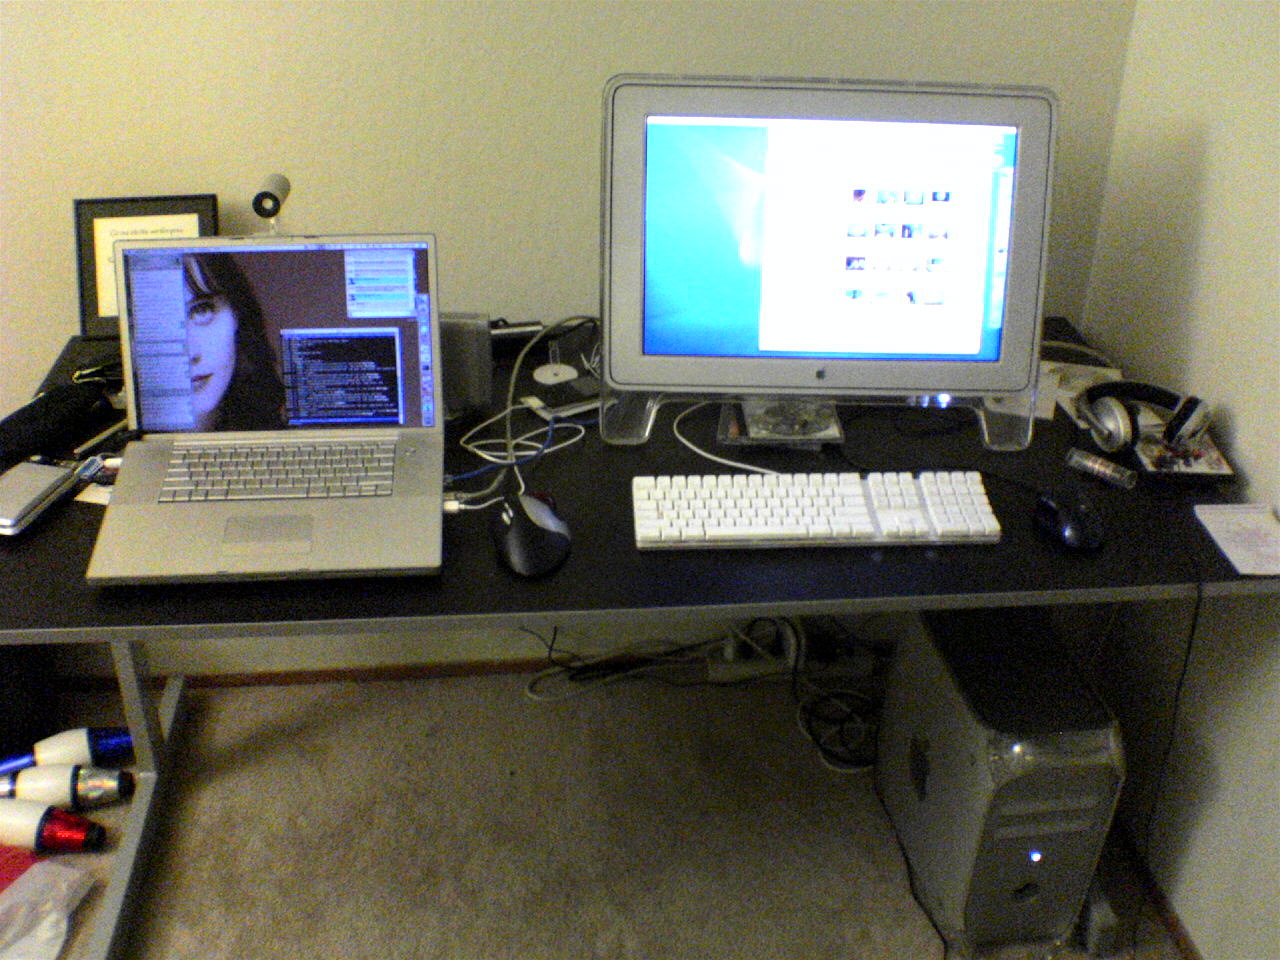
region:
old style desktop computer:
[575, 51, 1205, 937]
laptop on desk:
[53, 181, 480, 654]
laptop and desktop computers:
[57, 77, 1177, 923]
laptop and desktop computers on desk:
[55, 84, 1091, 950]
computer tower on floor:
[854, 604, 1144, 955]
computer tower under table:
[854, 567, 1135, 949]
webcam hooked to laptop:
[238, 117, 323, 288]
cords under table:
[591, 620, 914, 850]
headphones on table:
[1061, 351, 1232, 528]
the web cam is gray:
[248, 172, 291, 243]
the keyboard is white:
[630, 467, 1001, 552]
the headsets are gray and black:
[1075, 379, 1212, 450]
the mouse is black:
[1036, 477, 1107, 551]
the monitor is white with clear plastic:
[594, 75, 1060, 451]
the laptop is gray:
[84, 232, 446, 584]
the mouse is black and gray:
[491, 488, 571, 584]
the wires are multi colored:
[442, 311, 1211, 958]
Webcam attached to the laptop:
[246, 174, 293, 239]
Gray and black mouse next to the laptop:
[490, 490, 579, 585]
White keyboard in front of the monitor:
[630, 467, 999, 543]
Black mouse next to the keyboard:
[1033, 470, 1111, 557]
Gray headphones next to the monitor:
[1069, 373, 1213, 458]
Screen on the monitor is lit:
[643, 114, 1008, 368]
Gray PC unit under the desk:
[870, 620, 1120, 952]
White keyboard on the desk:
[619, 461, 1003, 548]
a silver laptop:
[87, 235, 434, 569]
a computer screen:
[605, 74, 1027, 383]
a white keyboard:
[629, 471, 987, 536]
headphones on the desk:
[1073, 376, 1201, 430]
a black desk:
[24, 331, 1272, 685]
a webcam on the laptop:
[244, 174, 297, 227]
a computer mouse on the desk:
[1020, 471, 1109, 553]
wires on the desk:
[475, 305, 612, 464]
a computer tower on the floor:
[872, 654, 1100, 931]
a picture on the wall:
[66, 201, 226, 325]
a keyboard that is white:
[627, 458, 1023, 551]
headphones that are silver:
[1058, 361, 1211, 463]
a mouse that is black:
[1034, 482, 1116, 567]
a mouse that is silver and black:
[457, 491, 577, 584]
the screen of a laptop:
[104, 262, 449, 430]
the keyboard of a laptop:
[164, 438, 407, 502]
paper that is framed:
[51, 189, 226, 333]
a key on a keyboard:
[649, 460, 680, 487]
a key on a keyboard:
[731, 471, 745, 489]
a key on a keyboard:
[749, 475, 763, 484]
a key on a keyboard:
[764, 468, 780, 488]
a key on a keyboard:
[777, 473, 789, 485]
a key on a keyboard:
[791, 462, 811, 491]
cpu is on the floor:
[892, 674, 1151, 948]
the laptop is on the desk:
[117, 250, 444, 586]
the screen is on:
[654, 102, 1019, 368]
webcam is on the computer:
[239, 175, 313, 231]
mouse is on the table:
[484, 471, 562, 635]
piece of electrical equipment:
[1057, 348, 1210, 476]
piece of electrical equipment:
[591, 59, 1068, 441]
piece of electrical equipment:
[77, 236, 459, 585]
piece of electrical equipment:
[483, 496, 559, 587]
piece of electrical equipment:
[231, 147, 309, 221]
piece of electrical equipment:
[4, 441, 91, 563]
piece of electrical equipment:
[662, 605, 833, 696]